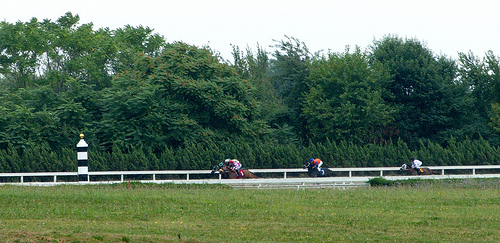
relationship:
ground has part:
[6, 176, 498, 242] [174, 191, 390, 233]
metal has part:
[0, 162, 499, 184] [276, 170, 299, 171]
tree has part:
[291, 56, 388, 143] [322, 90, 361, 121]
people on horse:
[225, 158, 242, 177] [211, 162, 257, 179]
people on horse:
[309, 158, 324, 172] [300, 162, 329, 178]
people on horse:
[407, 157, 423, 171] [399, 162, 432, 174]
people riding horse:
[225, 158, 242, 177] [211, 162, 257, 179]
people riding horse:
[309, 158, 324, 172] [300, 162, 329, 178]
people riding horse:
[407, 157, 423, 171] [399, 162, 432, 174]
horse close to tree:
[211, 162, 257, 179] [291, 56, 388, 143]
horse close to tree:
[399, 162, 432, 174] [291, 56, 388, 143]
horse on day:
[211, 162, 257, 179] [3, 2, 499, 240]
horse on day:
[300, 162, 329, 178] [3, 2, 499, 240]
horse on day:
[399, 162, 432, 174] [3, 2, 499, 240]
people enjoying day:
[225, 158, 242, 177] [3, 2, 499, 240]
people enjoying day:
[309, 158, 324, 172] [3, 2, 499, 240]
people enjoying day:
[407, 157, 423, 171] [3, 2, 499, 240]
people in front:
[225, 158, 242, 177] [202, 148, 260, 193]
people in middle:
[309, 158, 324, 172] [303, 151, 338, 188]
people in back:
[407, 157, 423, 171] [392, 146, 437, 188]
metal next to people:
[0, 162, 499, 184] [225, 158, 242, 177]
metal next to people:
[0, 162, 499, 184] [309, 158, 324, 172]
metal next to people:
[0, 162, 499, 184] [407, 157, 423, 171]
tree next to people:
[291, 56, 388, 143] [225, 158, 242, 177]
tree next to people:
[291, 56, 388, 143] [309, 158, 324, 172]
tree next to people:
[291, 56, 388, 143] [407, 157, 423, 171]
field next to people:
[6, 176, 498, 242] [225, 158, 242, 177]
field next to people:
[6, 176, 498, 242] [309, 158, 324, 172]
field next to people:
[6, 176, 498, 242] [407, 157, 423, 171]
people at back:
[407, 157, 423, 171] [392, 146, 437, 188]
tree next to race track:
[291, 56, 388, 143] [0, 162, 498, 242]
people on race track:
[225, 158, 242, 177] [0, 162, 498, 242]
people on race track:
[309, 158, 324, 172] [0, 162, 498, 242]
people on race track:
[407, 157, 423, 171] [0, 162, 498, 242]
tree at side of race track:
[291, 56, 388, 143] [0, 162, 498, 242]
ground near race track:
[6, 176, 498, 242] [0, 162, 498, 242]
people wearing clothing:
[309, 158, 324, 172] [313, 157, 322, 165]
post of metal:
[76, 138, 89, 173] [0, 162, 499, 184]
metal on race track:
[0, 162, 499, 184] [0, 162, 498, 242]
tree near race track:
[291, 56, 388, 143] [0, 162, 498, 242]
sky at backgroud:
[2, 2, 498, 68] [5, 1, 500, 94]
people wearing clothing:
[407, 157, 423, 171] [412, 160, 424, 171]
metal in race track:
[0, 162, 499, 184] [0, 162, 498, 242]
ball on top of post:
[77, 131, 87, 138] [76, 138, 89, 173]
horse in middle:
[300, 162, 329, 178] [303, 151, 338, 188]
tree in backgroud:
[291, 56, 388, 143] [5, 1, 500, 94]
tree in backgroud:
[108, 41, 260, 154] [5, 1, 500, 94]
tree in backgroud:
[366, 38, 462, 153] [5, 1, 500, 94]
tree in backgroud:
[10, 14, 94, 149] [5, 1, 500, 94]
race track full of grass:
[0, 162, 498, 242] [6, 176, 498, 242]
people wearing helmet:
[309, 158, 324, 172] [306, 157, 315, 167]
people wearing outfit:
[225, 158, 242, 177] [228, 159, 241, 172]